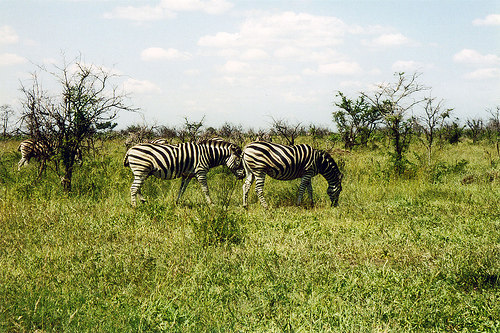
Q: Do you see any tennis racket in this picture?
A: No, there are no rackets.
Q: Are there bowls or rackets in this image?
A: No, there are no rackets or bowls.